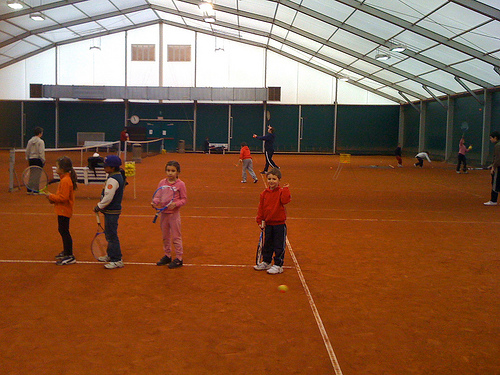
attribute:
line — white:
[297, 276, 317, 307]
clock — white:
[129, 115, 139, 125]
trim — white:
[124, 134, 162, 147]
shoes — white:
[242, 253, 302, 293]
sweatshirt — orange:
[38, 173, 83, 218]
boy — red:
[249, 166, 291, 281]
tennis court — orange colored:
[0, 150, 500, 374]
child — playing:
[390, 132, 411, 170]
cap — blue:
[97, 157, 127, 170]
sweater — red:
[252, 187, 324, 232]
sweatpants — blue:
[246, 211, 313, 263]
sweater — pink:
[150, 175, 188, 212]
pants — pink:
[159, 212, 183, 260]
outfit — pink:
[149, 170, 189, 258]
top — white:
[417, 149, 429, 160]